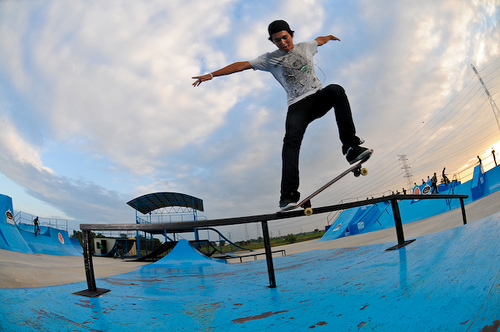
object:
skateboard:
[276, 149, 374, 217]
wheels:
[305, 208, 313, 216]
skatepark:
[0, 192, 498, 324]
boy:
[191, 20, 373, 211]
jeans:
[279, 84, 365, 204]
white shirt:
[248, 40, 324, 107]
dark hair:
[268, 30, 292, 37]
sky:
[0, 0, 500, 185]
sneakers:
[345, 145, 371, 165]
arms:
[213, 52, 268, 78]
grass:
[271, 231, 328, 247]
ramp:
[124, 240, 235, 282]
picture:
[4, 1, 500, 329]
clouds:
[0, 0, 497, 224]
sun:
[456, 138, 500, 166]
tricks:
[277, 107, 378, 222]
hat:
[268, 20, 295, 44]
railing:
[1, 150, 500, 254]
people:
[430, 172, 439, 194]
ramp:
[318, 185, 482, 242]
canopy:
[125, 192, 204, 216]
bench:
[225, 250, 286, 265]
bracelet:
[209, 73, 213, 79]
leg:
[280, 105, 316, 201]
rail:
[79, 195, 469, 231]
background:
[0, 4, 184, 176]